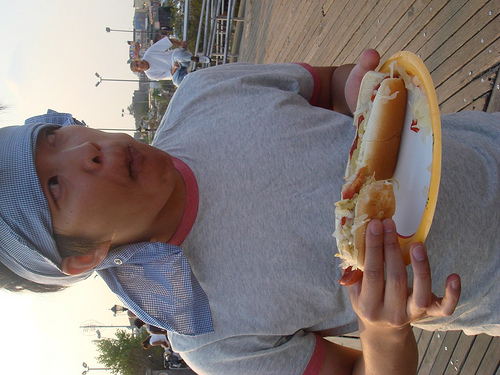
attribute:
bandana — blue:
[0, 109, 215, 336]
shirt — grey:
[148, 62, 500, 375]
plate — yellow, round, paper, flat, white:
[374, 50, 442, 266]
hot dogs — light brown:
[332, 70, 406, 288]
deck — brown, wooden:
[237, 0, 499, 374]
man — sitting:
[130, 35, 211, 90]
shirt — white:
[143, 35, 176, 82]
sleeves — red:
[296, 62, 322, 375]